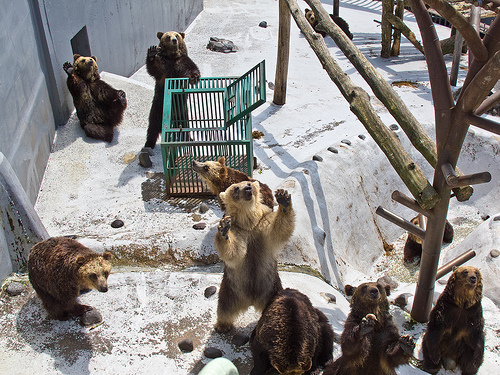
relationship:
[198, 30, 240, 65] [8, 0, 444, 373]
small stone on ground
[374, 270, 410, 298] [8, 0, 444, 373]
small stone on ground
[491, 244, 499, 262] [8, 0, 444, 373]
small stone visible on ground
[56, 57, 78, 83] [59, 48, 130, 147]
foot of bear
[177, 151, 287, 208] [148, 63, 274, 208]
bear in front of green cage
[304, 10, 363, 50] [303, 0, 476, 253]
bear almost hidden between poles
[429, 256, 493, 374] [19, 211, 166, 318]
happy faced bear by bear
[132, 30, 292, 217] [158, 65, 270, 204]
cage in bear enclosure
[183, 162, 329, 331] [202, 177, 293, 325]
bear that standing on two legs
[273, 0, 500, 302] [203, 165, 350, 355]
trees in the closure for bear